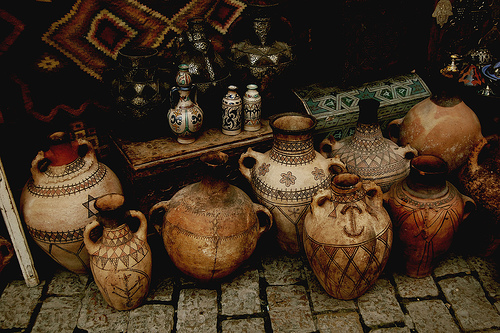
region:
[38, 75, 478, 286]
Row of pottery on ground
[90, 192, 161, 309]
Individual pot on ground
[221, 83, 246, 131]
Small white flask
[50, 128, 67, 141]
Opening of jug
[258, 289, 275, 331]
Groove between bricks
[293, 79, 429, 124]
Turquoise chest behind pots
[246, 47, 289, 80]
Part of jug is shiny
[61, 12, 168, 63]
Large checkered pattern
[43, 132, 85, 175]
Neck of jug is red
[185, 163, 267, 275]
Pot is brown and dirty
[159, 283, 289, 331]
gray brick floor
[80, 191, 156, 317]
beige urn with a tree design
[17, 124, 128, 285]
large beige urn with a red cap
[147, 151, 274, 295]
round light brown urn with a narrow neck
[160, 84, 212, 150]
small ceramic ewer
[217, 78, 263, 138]
pair of decorated white jugs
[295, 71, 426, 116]
blue-green and gray tiles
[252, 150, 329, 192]
floral design on a white urn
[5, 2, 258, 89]
carpet with diamond design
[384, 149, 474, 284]
reddish brown urn with dark lines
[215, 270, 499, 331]
The ground is made of brick.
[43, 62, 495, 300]
Vases on the ground.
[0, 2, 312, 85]
Blanket over the wall.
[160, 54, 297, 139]
Vases on a table.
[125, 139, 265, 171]
The table is brown.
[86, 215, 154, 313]
The vase has a design.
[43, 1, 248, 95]
Design on the blanket.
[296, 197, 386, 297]
Design on the vase.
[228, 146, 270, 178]
Handle on the vase.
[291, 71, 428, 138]
Table behind the vases.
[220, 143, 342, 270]
the jars are visible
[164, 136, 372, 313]
the jars are visible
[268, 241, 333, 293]
the jars are visible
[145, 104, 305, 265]
the jars are visible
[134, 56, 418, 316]
the jars are visible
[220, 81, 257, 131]
the two small vases side by side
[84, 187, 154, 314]
the two handled vase on the bottom left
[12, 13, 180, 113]
the fabric hanging in the back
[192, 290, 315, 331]
the brick cement ground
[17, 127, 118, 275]
the big vase on the bottom far left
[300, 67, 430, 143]
the green box in the back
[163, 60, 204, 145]
the two handled white vase on the shelf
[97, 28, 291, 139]
the vases on the shelf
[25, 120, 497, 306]
the vases on the ground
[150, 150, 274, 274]
the big vase shaped like a circle